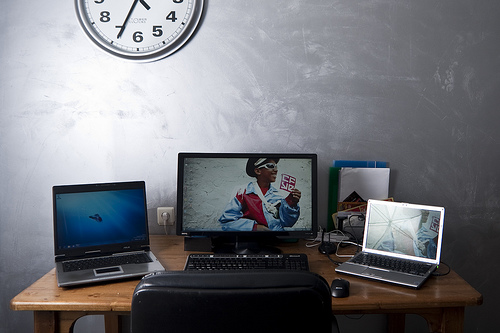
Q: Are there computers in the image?
A: Yes, there is a computer.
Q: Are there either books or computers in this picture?
A: Yes, there is a computer.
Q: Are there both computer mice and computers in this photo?
A: Yes, there are both a computer and a computer mouse.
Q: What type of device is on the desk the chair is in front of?
A: The device is a computer.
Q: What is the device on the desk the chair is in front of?
A: The device is a computer.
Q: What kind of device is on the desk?
A: The device is a computer.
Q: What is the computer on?
A: The computer is on the desk.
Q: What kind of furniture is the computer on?
A: The computer is on the desk.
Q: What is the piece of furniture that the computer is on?
A: The piece of furniture is a desk.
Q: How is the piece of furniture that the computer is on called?
A: The piece of furniture is a desk.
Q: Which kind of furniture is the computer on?
A: The computer is on the desk.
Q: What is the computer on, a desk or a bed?
A: The computer is on a desk.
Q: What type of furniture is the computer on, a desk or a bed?
A: The computer is on a desk.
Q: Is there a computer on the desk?
A: Yes, there is a computer on the desk.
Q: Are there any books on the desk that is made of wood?
A: No, there is a computer on the desk.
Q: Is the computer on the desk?
A: Yes, the computer is on the desk.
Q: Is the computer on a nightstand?
A: No, the computer is on the desk.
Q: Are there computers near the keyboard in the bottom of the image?
A: Yes, there is a computer near the keyboard.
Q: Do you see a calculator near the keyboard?
A: No, there is a computer near the keyboard.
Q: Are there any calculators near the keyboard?
A: No, there is a computer near the keyboard.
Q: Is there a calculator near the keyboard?
A: No, there is a computer near the keyboard.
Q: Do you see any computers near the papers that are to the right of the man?
A: Yes, there is a computer near the papers.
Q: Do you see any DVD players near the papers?
A: No, there is a computer near the papers.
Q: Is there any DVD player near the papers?
A: No, there is a computer near the papers.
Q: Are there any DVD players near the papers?
A: No, there is a computer near the papers.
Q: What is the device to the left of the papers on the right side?
A: The device is a computer.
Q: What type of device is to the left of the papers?
A: The device is a computer.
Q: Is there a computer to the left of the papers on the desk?
A: Yes, there is a computer to the left of the papers.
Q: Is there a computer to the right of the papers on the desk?
A: No, the computer is to the left of the papers.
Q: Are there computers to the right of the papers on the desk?
A: No, the computer is to the left of the papers.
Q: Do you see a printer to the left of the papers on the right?
A: No, there is a computer to the left of the papers.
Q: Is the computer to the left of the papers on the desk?
A: Yes, the computer is to the left of the papers.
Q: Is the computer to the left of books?
A: No, the computer is to the left of the papers.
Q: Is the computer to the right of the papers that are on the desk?
A: No, the computer is to the left of the papers.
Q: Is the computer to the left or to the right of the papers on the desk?
A: The computer is to the left of the papers.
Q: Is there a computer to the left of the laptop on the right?
A: Yes, there is a computer to the left of the laptop.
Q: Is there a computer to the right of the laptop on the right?
A: No, the computer is to the left of the laptop.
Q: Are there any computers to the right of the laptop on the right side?
A: No, the computer is to the left of the laptop.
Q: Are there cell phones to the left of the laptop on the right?
A: No, there is a computer to the left of the laptop computer.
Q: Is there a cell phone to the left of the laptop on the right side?
A: No, there is a computer to the left of the laptop computer.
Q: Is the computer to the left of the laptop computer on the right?
A: Yes, the computer is to the left of the laptop.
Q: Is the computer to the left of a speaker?
A: No, the computer is to the left of the laptop.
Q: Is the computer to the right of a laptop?
A: No, the computer is to the left of a laptop.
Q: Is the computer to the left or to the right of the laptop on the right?
A: The computer is to the left of the laptop.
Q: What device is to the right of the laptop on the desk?
A: The device is a computer.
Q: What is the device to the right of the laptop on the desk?
A: The device is a computer.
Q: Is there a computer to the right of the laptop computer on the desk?
A: Yes, there is a computer to the right of the laptop.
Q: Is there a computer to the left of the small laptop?
A: No, the computer is to the right of the laptop.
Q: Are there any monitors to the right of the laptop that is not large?
A: No, there is a computer to the right of the laptop computer.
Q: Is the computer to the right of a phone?
A: No, the computer is to the right of a laptop.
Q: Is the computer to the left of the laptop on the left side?
A: No, the computer is to the right of the laptop.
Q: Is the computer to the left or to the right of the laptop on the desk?
A: The computer is to the right of the laptop computer.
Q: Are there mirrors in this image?
A: No, there are no mirrors.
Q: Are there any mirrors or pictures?
A: No, there are no mirrors or pictures.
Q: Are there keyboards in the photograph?
A: Yes, there is a keyboard.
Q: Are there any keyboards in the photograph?
A: Yes, there is a keyboard.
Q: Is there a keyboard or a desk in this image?
A: Yes, there is a keyboard.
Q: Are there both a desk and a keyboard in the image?
A: Yes, there are both a keyboard and a desk.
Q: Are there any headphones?
A: No, there are no headphones.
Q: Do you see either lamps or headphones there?
A: No, there are no headphones or lamps.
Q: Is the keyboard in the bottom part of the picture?
A: Yes, the keyboard is in the bottom of the image.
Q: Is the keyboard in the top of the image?
A: No, the keyboard is in the bottom of the image.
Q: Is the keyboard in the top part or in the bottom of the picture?
A: The keyboard is in the bottom of the image.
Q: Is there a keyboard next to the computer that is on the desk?
A: Yes, there is a keyboard next to the computer.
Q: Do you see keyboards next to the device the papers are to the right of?
A: Yes, there is a keyboard next to the computer.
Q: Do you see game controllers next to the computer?
A: No, there is a keyboard next to the computer.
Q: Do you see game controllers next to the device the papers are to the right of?
A: No, there is a keyboard next to the computer.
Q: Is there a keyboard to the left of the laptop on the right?
A: Yes, there is a keyboard to the left of the laptop.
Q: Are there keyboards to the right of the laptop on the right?
A: No, the keyboard is to the left of the laptop.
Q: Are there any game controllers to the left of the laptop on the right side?
A: No, there is a keyboard to the left of the laptop computer.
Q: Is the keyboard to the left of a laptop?
A: Yes, the keyboard is to the left of a laptop.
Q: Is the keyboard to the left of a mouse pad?
A: No, the keyboard is to the left of a laptop.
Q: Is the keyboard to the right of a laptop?
A: No, the keyboard is to the left of a laptop.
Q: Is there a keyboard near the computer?
A: Yes, there is a keyboard near the computer.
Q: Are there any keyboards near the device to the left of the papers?
A: Yes, there is a keyboard near the computer.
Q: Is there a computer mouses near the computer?
A: No, there is a keyboard near the computer.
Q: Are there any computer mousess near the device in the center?
A: No, there is a keyboard near the computer.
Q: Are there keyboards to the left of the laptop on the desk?
A: No, the keyboard is to the right of the laptop.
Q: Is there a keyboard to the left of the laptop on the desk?
A: No, the keyboard is to the right of the laptop.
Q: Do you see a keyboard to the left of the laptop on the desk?
A: No, the keyboard is to the right of the laptop.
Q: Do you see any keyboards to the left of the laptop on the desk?
A: No, the keyboard is to the right of the laptop.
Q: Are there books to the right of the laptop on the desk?
A: No, there is a keyboard to the right of the laptop computer.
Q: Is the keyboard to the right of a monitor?
A: No, the keyboard is to the right of a laptop.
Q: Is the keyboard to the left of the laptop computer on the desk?
A: No, the keyboard is to the right of the laptop computer.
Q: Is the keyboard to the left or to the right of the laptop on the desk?
A: The keyboard is to the right of the laptop computer.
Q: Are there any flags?
A: No, there are no flags.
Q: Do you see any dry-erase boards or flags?
A: No, there are no flags or dry-erase boards.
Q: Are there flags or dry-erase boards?
A: No, there are no flags or dry-erase boards.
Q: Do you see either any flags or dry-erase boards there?
A: No, there are no flags or dry-erase boards.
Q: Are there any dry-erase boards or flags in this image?
A: No, there are no flags or dry-erase boards.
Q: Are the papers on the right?
A: Yes, the papers are on the right of the image.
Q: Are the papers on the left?
A: No, the papers are on the right of the image.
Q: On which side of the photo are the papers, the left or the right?
A: The papers are on the right of the image.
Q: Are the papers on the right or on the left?
A: The papers are on the right of the image.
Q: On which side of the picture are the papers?
A: The papers are on the right of the image.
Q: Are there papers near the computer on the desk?
A: Yes, there are papers near the computer.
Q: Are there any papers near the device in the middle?
A: Yes, there are papers near the computer.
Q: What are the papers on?
A: The papers are on the desk.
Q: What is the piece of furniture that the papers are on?
A: The piece of furniture is a desk.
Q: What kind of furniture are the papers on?
A: The papers are on the desk.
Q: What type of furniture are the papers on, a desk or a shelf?
A: The papers are on a desk.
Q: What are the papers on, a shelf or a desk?
A: The papers are on a desk.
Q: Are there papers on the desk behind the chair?
A: Yes, there are papers on the desk.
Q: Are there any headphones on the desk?
A: No, there are papers on the desk.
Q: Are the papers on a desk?
A: Yes, the papers are on a desk.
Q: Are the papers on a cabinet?
A: No, the papers are on a desk.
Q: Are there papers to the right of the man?
A: Yes, there are papers to the right of the man.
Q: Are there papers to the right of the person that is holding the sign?
A: Yes, there are papers to the right of the man.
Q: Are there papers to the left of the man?
A: No, the papers are to the right of the man.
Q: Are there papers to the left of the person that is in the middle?
A: No, the papers are to the right of the man.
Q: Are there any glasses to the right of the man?
A: No, there are papers to the right of the man.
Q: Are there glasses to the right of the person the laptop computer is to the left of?
A: No, there are papers to the right of the man.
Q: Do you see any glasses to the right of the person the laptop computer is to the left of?
A: No, there are papers to the right of the man.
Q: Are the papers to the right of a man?
A: Yes, the papers are to the right of a man.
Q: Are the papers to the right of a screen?
A: No, the papers are to the right of a man.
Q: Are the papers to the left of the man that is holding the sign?
A: No, the papers are to the right of the man.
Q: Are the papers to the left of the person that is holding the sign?
A: No, the papers are to the right of the man.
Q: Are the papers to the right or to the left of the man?
A: The papers are to the right of the man.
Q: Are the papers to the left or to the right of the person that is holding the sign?
A: The papers are to the right of the man.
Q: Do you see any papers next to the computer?
A: Yes, there are papers next to the computer.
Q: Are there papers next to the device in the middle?
A: Yes, there are papers next to the computer.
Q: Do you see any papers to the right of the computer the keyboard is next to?
A: Yes, there are papers to the right of the computer.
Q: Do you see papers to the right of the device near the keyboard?
A: Yes, there are papers to the right of the computer.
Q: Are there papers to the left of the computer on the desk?
A: No, the papers are to the right of the computer.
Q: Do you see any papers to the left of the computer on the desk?
A: No, the papers are to the right of the computer.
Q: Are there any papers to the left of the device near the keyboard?
A: No, the papers are to the right of the computer.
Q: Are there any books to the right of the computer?
A: No, there are papers to the right of the computer.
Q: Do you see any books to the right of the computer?
A: No, there are papers to the right of the computer.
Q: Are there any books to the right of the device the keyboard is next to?
A: No, there are papers to the right of the computer.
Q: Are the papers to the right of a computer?
A: Yes, the papers are to the right of a computer.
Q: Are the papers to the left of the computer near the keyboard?
A: No, the papers are to the right of the computer.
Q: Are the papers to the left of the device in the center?
A: No, the papers are to the right of the computer.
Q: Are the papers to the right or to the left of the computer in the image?
A: The papers are to the right of the computer.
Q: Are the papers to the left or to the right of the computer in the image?
A: The papers are to the right of the computer.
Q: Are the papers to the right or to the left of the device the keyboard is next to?
A: The papers are to the right of the computer.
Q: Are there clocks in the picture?
A: Yes, there is a clock.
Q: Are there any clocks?
A: Yes, there is a clock.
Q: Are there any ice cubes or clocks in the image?
A: Yes, there is a clock.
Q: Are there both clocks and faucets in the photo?
A: No, there is a clock but no faucets.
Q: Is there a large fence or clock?
A: Yes, there is a large clock.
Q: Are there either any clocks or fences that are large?
A: Yes, the clock is large.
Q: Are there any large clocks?
A: Yes, there is a large clock.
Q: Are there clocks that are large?
A: Yes, there is a clock that is large.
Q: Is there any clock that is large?
A: Yes, there is a clock that is large.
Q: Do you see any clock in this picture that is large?
A: Yes, there is a clock that is large.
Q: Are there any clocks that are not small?
A: Yes, there is a large clock.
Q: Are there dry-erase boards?
A: No, there are no dry-erase boards.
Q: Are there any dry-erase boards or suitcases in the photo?
A: No, there are no dry-erase boards or suitcases.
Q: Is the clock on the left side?
A: Yes, the clock is on the left of the image.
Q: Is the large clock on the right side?
A: No, the clock is on the left of the image.